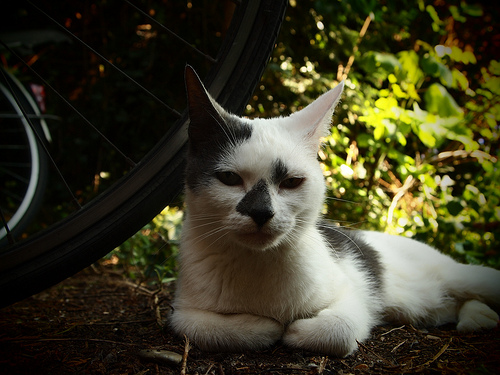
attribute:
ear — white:
[296, 76, 347, 146]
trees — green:
[322, 21, 497, 247]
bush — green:
[347, 44, 487, 225]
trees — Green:
[103, 0, 498, 266]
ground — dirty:
[14, 259, 497, 374]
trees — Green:
[110, 2, 498, 303]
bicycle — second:
[11, 14, 291, 297]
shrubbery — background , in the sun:
[333, 80, 497, 245]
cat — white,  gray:
[153, 98, 498, 343]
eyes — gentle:
[212, 170, 308, 190]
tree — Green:
[350, 34, 406, 229]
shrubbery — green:
[319, 9, 499, 226]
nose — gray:
[243, 207, 279, 220]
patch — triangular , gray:
[230, 174, 285, 226]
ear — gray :
[177, 59, 246, 166]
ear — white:
[281, 70, 351, 153]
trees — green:
[134, 23, 482, 293]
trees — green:
[129, 23, 455, 275]